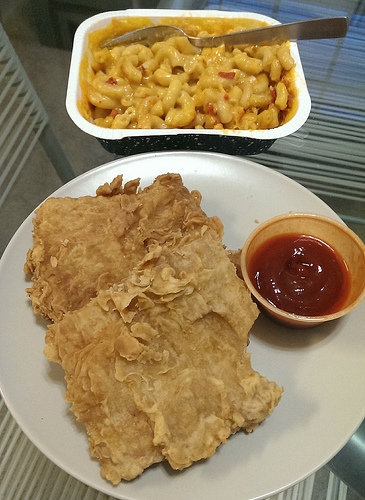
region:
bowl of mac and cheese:
[63, 9, 301, 155]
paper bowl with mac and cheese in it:
[64, 12, 307, 153]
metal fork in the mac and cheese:
[97, 15, 347, 53]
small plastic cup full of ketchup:
[241, 214, 360, 325]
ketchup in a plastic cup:
[240, 212, 364, 327]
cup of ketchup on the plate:
[239, 212, 364, 325]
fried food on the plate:
[22, 172, 279, 484]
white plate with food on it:
[1, 149, 363, 498]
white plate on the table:
[6, 150, 364, 498]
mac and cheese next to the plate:
[64, 12, 308, 154]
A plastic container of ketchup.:
[236, 209, 363, 325]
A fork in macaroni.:
[105, 15, 350, 49]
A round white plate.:
[0, 148, 363, 498]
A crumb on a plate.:
[251, 216, 260, 224]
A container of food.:
[63, 8, 348, 156]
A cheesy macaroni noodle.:
[168, 91, 196, 127]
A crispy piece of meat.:
[22, 170, 285, 487]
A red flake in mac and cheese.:
[217, 68, 237, 81]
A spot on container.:
[193, 140, 204, 148]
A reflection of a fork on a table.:
[289, 125, 313, 141]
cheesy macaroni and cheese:
[69, 0, 363, 155]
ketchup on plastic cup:
[230, 182, 359, 325]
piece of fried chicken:
[45, 231, 310, 481]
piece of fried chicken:
[24, 155, 237, 307]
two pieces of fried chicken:
[19, 169, 291, 486]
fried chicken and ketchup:
[18, 178, 361, 498]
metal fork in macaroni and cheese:
[101, 0, 354, 70]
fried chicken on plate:
[8, 167, 364, 492]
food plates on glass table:
[0, 1, 360, 497]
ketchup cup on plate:
[236, 213, 362, 333]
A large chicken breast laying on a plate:
[25, 170, 284, 482]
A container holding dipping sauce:
[237, 207, 363, 330]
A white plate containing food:
[1, 147, 364, 496]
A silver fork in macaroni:
[94, 12, 357, 55]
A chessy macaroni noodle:
[154, 47, 184, 71]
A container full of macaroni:
[56, 4, 318, 161]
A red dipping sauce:
[250, 231, 353, 311]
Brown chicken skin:
[58, 183, 207, 279]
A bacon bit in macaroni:
[210, 66, 244, 81]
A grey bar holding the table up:
[313, 406, 363, 497]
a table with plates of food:
[8, 5, 364, 493]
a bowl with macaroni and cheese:
[65, 12, 301, 152]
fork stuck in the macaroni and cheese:
[113, 15, 347, 49]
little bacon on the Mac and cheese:
[217, 70, 235, 79]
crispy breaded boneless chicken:
[19, 172, 289, 486]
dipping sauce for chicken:
[237, 212, 363, 329]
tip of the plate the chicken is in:
[93, 146, 281, 170]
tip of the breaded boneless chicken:
[158, 445, 202, 470]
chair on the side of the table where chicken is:
[0, 22, 68, 181]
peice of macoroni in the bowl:
[118, 52, 146, 79]